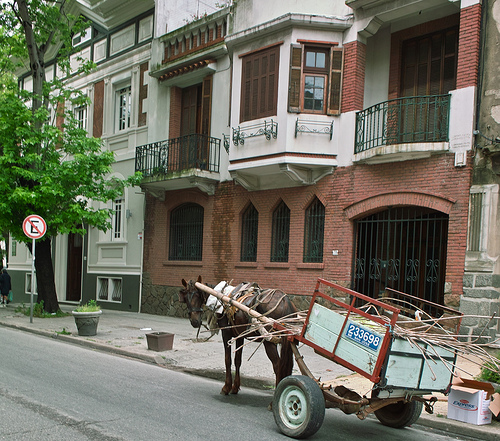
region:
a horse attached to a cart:
[168, 258, 305, 388]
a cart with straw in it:
[306, 270, 471, 397]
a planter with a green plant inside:
[68, 294, 125, 348]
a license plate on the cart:
[346, 326, 383, 361]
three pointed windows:
[231, 196, 326, 286]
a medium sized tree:
[6, 70, 118, 330]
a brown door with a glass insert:
[61, 216, 98, 306]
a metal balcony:
[118, 104, 232, 196]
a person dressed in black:
[1, 260, 31, 302]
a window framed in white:
[91, 178, 136, 255]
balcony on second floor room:
[139, 62, 224, 187]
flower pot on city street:
[60, 293, 107, 358]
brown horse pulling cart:
[166, 258, 498, 438]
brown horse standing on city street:
[181, 261, 299, 395]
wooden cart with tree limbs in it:
[287, 274, 454, 439]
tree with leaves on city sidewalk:
[5, 71, 119, 335]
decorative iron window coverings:
[235, 190, 337, 274]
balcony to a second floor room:
[351, 16, 478, 171]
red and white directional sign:
[21, 203, 55, 326]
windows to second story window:
[219, 33, 367, 150]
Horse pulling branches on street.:
[168, 265, 475, 437]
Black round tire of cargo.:
[252, 372, 339, 434]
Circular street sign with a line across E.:
[10, 206, 60, 242]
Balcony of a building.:
[347, 16, 477, 161]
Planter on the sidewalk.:
[70, 290, 100, 341]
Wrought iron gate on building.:
[350, 206, 440, 301]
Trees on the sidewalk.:
[10, 5, 122, 345]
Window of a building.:
[100, 80, 145, 127]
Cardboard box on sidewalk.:
[442, 371, 494, 431]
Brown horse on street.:
[171, 265, 312, 415]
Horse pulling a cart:
[170, 262, 478, 439]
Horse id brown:
[175, 260, 300, 409]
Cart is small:
[265, 264, 469, 439]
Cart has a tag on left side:
[337, 315, 389, 362]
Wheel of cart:
[258, 367, 327, 439]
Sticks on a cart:
[220, 264, 499, 371]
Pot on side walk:
[68, 290, 110, 343]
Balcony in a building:
[125, 74, 228, 194]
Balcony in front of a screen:
[343, 10, 465, 165]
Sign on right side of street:
[12, 204, 63, 336]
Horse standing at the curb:
[165, 270, 349, 430]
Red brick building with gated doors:
[151, 104, 466, 317]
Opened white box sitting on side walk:
[432, 362, 497, 433]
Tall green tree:
[3, 60, 118, 336]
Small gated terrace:
[128, 59, 252, 201]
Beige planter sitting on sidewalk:
[68, 290, 122, 353]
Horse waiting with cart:
[161, 261, 461, 439]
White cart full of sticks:
[283, 279, 498, 419]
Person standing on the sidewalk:
[0, 263, 12, 335]